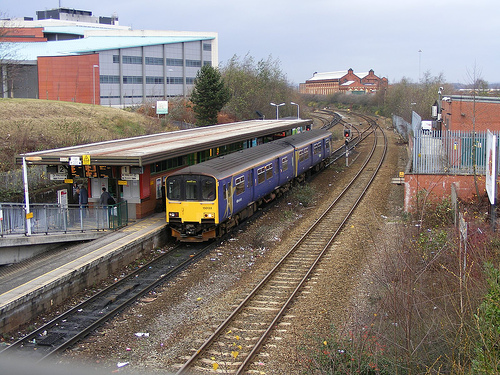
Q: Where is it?
A: This is at the train station.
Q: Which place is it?
A: It is a train station.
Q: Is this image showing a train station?
A: Yes, it is showing a train station.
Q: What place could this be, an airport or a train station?
A: It is a train station.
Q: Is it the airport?
A: No, it is the train station.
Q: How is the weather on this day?
A: It is clear.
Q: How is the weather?
A: It is clear.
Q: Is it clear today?
A: Yes, it is clear.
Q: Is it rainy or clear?
A: It is clear.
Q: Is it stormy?
A: No, it is clear.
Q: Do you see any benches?
A: No, there are no benches.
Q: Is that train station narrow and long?
A: Yes, the train station is narrow and long.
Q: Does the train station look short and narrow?
A: No, the train station is narrow but long.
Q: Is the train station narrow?
A: Yes, the train station is narrow.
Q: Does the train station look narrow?
A: Yes, the train station is narrow.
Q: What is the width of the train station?
A: The train station is narrow.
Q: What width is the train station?
A: The train station is narrow.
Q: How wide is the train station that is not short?
A: The train station is narrow.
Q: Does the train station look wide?
A: No, the train station is narrow.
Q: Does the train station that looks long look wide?
A: No, the train station is narrow.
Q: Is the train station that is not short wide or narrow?
A: The train station is narrow.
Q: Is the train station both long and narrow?
A: Yes, the train station is long and narrow.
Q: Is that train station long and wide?
A: No, the train station is long but narrow.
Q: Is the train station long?
A: Yes, the train station is long.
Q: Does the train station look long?
A: Yes, the train station is long.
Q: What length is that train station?
A: The train station is long.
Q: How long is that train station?
A: The train station is long.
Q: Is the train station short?
A: No, the train station is long.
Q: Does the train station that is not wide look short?
A: No, the train station is long.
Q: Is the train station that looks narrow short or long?
A: The train station is long.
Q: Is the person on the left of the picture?
A: Yes, the person is on the left of the image.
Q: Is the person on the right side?
A: No, the person is on the left of the image.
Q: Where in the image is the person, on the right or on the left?
A: The person is on the left of the image.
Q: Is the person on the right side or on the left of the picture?
A: The person is on the left of the image.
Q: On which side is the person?
A: The person is on the left of the image.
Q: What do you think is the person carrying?
A: The person is carrying a backpack.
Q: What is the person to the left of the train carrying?
A: The person is carrying a backpack.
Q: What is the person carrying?
A: The person is carrying a backpack.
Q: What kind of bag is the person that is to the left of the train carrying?
A: The person is carrying a backpack.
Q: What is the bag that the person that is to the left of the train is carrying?
A: The bag is a backpack.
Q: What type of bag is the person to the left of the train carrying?
A: The person is carrying a backpack.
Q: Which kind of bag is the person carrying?
A: The person is carrying a backpack.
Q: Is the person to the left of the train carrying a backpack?
A: Yes, the person is carrying a backpack.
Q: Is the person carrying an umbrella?
A: No, the person is carrying a backpack.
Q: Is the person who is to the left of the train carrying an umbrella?
A: No, the person is carrying a backpack.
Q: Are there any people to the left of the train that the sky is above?
A: Yes, there is a person to the left of the train.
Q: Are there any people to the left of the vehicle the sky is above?
A: Yes, there is a person to the left of the train.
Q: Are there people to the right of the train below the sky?
A: No, the person is to the left of the train.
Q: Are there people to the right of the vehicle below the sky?
A: No, the person is to the left of the train.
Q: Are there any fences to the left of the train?
A: No, there is a person to the left of the train.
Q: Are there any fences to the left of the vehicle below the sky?
A: No, there is a person to the left of the train.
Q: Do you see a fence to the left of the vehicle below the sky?
A: No, there is a person to the left of the train.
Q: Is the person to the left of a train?
A: Yes, the person is to the left of a train.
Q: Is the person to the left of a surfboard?
A: No, the person is to the left of a train.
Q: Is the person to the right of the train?
A: No, the person is to the left of the train.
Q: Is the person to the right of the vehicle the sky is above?
A: No, the person is to the left of the train.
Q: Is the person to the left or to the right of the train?
A: The person is to the left of the train.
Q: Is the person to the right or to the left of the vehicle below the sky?
A: The person is to the left of the train.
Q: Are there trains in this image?
A: Yes, there is a train.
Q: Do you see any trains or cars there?
A: Yes, there is a train.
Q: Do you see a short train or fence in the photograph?
A: Yes, there is a short train.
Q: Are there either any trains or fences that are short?
A: Yes, the train is short.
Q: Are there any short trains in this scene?
A: Yes, there is a short train.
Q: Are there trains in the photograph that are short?
A: Yes, there is a train that is short.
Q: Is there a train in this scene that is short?
A: Yes, there is a train that is short.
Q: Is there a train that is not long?
A: Yes, there is a short train.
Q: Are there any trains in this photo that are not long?
A: Yes, there is a short train.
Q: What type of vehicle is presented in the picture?
A: The vehicle is a train.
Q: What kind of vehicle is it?
A: The vehicle is a train.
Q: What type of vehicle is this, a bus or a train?
A: That is a train.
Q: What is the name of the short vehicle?
A: The vehicle is a train.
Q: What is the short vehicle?
A: The vehicle is a train.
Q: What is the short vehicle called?
A: The vehicle is a train.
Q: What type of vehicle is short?
A: The vehicle is a train.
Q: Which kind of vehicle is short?
A: The vehicle is a train.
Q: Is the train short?
A: Yes, the train is short.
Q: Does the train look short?
A: Yes, the train is short.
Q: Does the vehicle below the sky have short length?
A: Yes, the train is short.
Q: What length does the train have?
A: The train has short length.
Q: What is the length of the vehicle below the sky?
A: The train is short.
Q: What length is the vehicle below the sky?
A: The train is short.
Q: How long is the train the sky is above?
A: The train is short.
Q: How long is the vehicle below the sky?
A: The train is short.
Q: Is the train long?
A: No, the train is short.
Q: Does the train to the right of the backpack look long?
A: No, the train is short.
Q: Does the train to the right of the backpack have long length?
A: No, the train is short.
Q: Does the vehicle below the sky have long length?
A: No, the train is short.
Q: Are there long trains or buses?
A: No, there is a train but it is short.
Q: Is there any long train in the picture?
A: No, there is a train but it is short.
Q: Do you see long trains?
A: No, there is a train but it is short.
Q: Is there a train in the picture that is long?
A: No, there is a train but it is short.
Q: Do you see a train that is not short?
A: No, there is a train but it is short.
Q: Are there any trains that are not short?
A: No, there is a train but it is short.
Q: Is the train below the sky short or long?
A: The train is short.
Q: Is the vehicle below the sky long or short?
A: The train is short.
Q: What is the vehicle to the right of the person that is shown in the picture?
A: The vehicle is a train.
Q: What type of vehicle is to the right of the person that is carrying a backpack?
A: The vehicle is a train.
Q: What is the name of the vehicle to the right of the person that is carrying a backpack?
A: The vehicle is a train.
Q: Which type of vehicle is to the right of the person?
A: The vehicle is a train.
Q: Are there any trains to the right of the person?
A: Yes, there is a train to the right of the person.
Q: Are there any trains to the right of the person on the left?
A: Yes, there is a train to the right of the person.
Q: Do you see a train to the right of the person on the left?
A: Yes, there is a train to the right of the person.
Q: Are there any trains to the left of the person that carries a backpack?
A: No, the train is to the right of the person.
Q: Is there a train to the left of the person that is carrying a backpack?
A: No, the train is to the right of the person.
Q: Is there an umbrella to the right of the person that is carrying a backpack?
A: No, there is a train to the right of the person.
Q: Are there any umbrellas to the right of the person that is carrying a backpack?
A: No, there is a train to the right of the person.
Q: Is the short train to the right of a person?
A: Yes, the train is to the right of a person.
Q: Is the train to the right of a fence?
A: No, the train is to the right of a person.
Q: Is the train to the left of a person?
A: No, the train is to the right of a person.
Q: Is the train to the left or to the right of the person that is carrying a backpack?
A: The train is to the right of the person.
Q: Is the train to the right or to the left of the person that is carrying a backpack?
A: The train is to the right of the person.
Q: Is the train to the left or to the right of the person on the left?
A: The train is to the right of the person.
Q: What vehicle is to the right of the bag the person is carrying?
A: The vehicle is a train.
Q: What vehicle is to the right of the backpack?
A: The vehicle is a train.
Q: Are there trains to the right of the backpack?
A: Yes, there is a train to the right of the backpack.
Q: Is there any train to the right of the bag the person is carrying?
A: Yes, there is a train to the right of the backpack.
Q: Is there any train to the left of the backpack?
A: No, the train is to the right of the backpack.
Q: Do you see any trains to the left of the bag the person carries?
A: No, the train is to the right of the backpack.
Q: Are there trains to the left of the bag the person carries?
A: No, the train is to the right of the backpack.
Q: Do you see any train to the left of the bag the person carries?
A: No, the train is to the right of the backpack.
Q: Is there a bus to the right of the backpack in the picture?
A: No, there is a train to the right of the backpack.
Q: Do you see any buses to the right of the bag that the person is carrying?
A: No, there is a train to the right of the backpack.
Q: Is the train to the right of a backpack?
A: Yes, the train is to the right of a backpack.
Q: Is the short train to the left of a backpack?
A: No, the train is to the right of a backpack.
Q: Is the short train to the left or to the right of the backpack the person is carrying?
A: The train is to the right of the backpack.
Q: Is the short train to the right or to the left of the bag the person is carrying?
A: The train is to the right of the backpack.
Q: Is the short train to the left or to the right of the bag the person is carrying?
A: The train is to the right of the backpack.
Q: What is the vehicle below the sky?
A: The vehicle is a train.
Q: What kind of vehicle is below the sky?
A: The vehicle is a train.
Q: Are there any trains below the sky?
A: Yes, there is a train below the sky.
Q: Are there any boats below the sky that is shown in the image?
A: No, there is a train below the sky.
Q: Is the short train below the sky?
A: Yes, the train is below the sky.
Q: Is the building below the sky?
A: Yes, the building is below the sky.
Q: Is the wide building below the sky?
A: Yes, the building is below the sky.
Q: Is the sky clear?
A: Yes, the sky is clear.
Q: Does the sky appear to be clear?
A: Yes, the sky is clear.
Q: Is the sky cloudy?
A: No, the sky is clear.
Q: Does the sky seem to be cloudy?
A: No, the sky is clear.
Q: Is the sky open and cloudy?
A: No, the sky is open but clear.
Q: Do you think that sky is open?
A: Yes, the sky is open.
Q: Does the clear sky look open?
A: Yes, the sky is open.